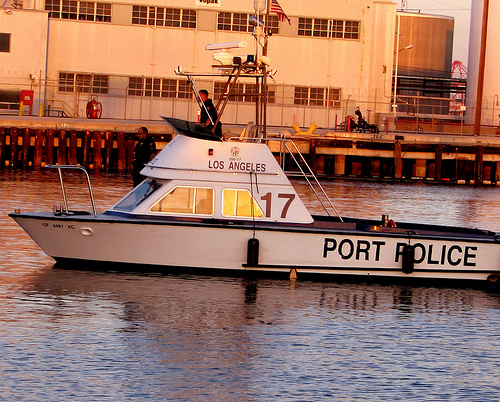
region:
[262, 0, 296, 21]
American flagon pole.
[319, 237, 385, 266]
The word Port on the side of the boat.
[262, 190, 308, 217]
The number 17 on the side of the boat.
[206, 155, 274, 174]
The words Los Angeles on the boat.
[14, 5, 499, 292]
Police boat sailing in water.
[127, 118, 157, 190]
Police officer wearing glasses.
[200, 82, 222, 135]
Police officer on upper deck.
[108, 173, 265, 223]
Windows to police boat.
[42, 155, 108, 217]
Metal railing on boat's front dock.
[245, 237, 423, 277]
Two black anchors on side of boat.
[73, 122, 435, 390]
the boat is white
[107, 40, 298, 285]
the boat is white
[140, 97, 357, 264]
the boat is white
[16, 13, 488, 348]
a police boat in harbor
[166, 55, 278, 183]
a cop piloting a boat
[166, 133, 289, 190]
the boat is from los angeles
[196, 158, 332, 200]
the font is black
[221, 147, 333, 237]
the boat number is 17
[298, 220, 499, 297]
the words are port police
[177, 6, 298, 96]
this is a radar system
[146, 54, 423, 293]
the ladder is white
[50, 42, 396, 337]
the boat has a cabin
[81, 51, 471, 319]
A police boat on the water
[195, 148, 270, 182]
Where the police boat is from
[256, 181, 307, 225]
The id numbe of the police boat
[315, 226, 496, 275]
The police department name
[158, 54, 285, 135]
Police officer driving the boat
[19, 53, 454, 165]
The docks on the waterfront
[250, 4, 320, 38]
A United States Flag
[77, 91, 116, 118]
Waterfron fire hose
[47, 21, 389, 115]
A buoldong on the waterfront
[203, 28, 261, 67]
the police boat radar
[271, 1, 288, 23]
American flag blowing in the wind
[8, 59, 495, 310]
small speedboat on the water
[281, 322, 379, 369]
tiny ripples in the water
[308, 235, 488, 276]
writing on the side of the boat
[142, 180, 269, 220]
windows on the side of the boat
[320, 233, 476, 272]
black writing in all caps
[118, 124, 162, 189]
man standing on the boat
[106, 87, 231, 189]
two police officers on the boat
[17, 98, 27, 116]
small yellow post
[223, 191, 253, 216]
light reflecting off the window